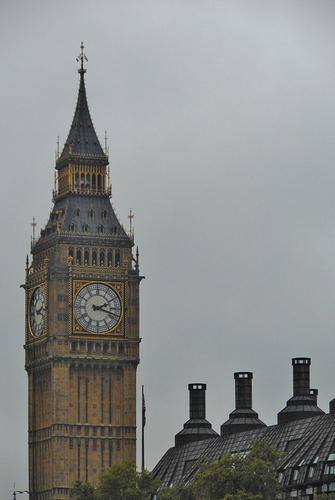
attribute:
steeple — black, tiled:
[55, 40, 110, 196]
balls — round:
[80, 40, 85, 49]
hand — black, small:
[93, 301, 109, 309]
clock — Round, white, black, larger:
[69, 277, 126, 339]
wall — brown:
[66, 365, 122, 424]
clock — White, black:
[71, 280, 123, 333]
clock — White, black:
[27, 285, 46, 338]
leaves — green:
[211, 468, 267, 489]